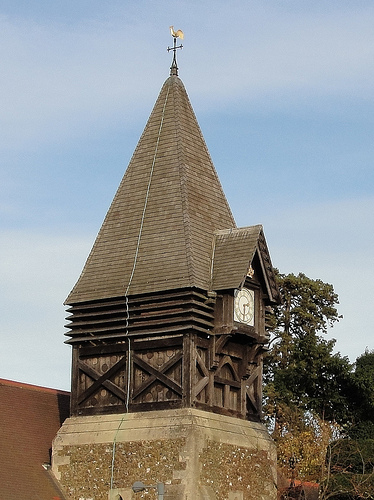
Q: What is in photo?
A: Tower.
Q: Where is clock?
A: On the front.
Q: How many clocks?
A: One.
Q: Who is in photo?
A: Noone.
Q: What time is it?
A: 2:30.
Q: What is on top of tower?
A: Rooster.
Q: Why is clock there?
A: Tell time.